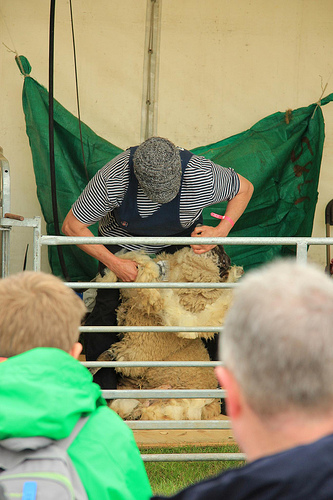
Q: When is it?
A: Daytime.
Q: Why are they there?
A: To watch.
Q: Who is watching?
A: People.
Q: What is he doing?
A: Shaving lamb.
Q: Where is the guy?
A: Behind fence.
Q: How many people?
A: 3.